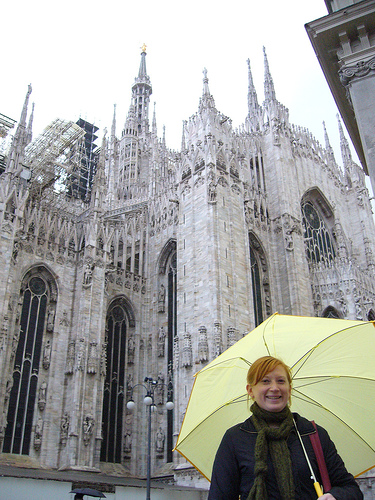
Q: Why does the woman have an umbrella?
A: It is rainy outside.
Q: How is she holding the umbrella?
A: Over her left shoulder.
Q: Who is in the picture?
A: A woman.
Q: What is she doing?
A: Smiling at the camera.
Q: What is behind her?
A: An old castle.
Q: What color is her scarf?
A: Green.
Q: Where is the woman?
A: In front of a castle.